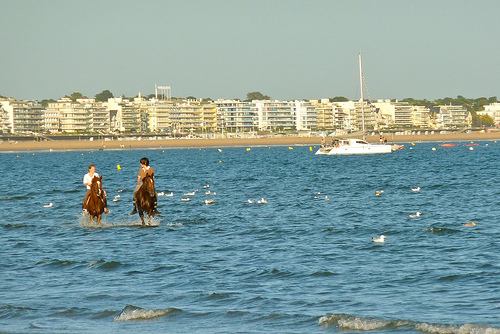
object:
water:
[0, 147, 500, 333]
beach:
[1, 132, 498, 151]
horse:
[82, 175, 110, 227]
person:
[81, 164, 106, 211]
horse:
[132, 174, 161, 225]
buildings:
[476, 99, 500, 131]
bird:
[371, 233, 387, 242]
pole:
[358, 53, 367, 142]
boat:
[315, 53, 396, 156]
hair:
[88, 164, 96, 169]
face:
[90, 166, 96, 174]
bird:
[408, 210, 423, 218]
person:
[131, 156, 162, 215]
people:
[333, 140, 342, 148]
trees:
[471, 112, 494, 128]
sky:
[1, 0, 500, 94]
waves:
[313, 304, 499, 334]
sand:
[1, 140, 78, 150]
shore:
[1, 129, 500, 148]